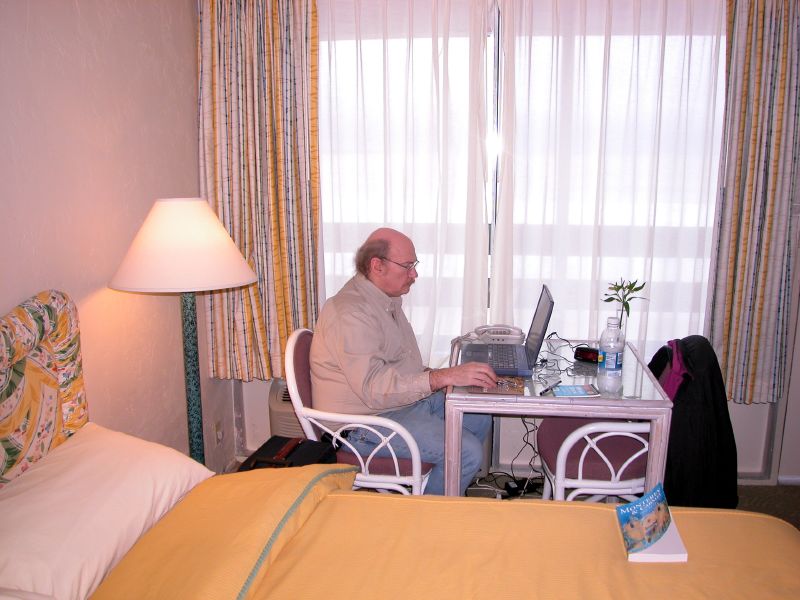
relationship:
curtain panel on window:
[185, 1, 331, 386] [187, 0, 798, 409]